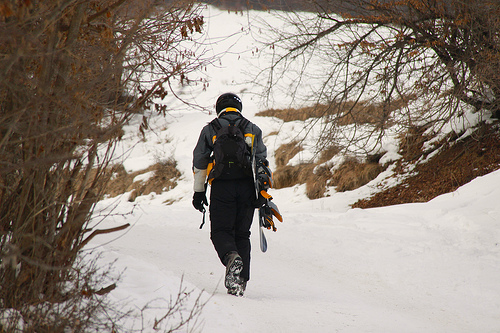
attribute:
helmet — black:
[218, 92, 240, 110]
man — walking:
[193, 78, 270, 286]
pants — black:
[206, 184, 237, 251]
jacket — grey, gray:
[217, 111, 252, 171]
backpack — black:
[225, 123, 276, 181]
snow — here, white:
[375, 282, 403, 295]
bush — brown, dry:
[93, 64, 142, 80]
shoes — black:
[229, 283, 257, 295]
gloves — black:
[180, 199, 220, 210]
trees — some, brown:
[371, 33, 469, 117]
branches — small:
[104, 6, 150, 24]